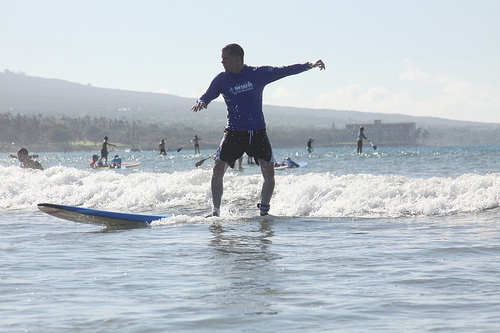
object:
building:
[344, 118, 430, 143]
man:
[189, 42, 325, 217]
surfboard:
[37, 202, 167, 232]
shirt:
[196, 61, 311, 132]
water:
[0, 147, 499, 332]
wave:
[0, 165, 499, 227]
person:
[279, 157, 300, 168]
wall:
[346, 118, 417, 143]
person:
[190, 134, 202, 155]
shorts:
[213, 126, 276, 168]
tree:
[41, 114, 77, 146]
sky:
[0, 0, 499, 124]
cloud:
[328, 66, 497, 96]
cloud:
[18, 16, 217, 63]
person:
[158, 138, 167, 156]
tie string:
[247, 130, 254, 146]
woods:
[0, 110, 102, 145]